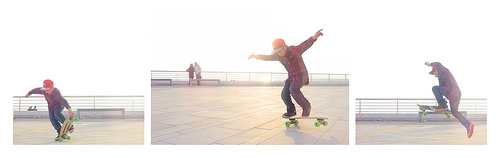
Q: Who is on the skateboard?
A: A man.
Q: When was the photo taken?
A: Day time.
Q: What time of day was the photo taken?
A: Afternoon.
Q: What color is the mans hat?
A: Red.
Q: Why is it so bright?
A: Sunny.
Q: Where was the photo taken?
A: At the beach.